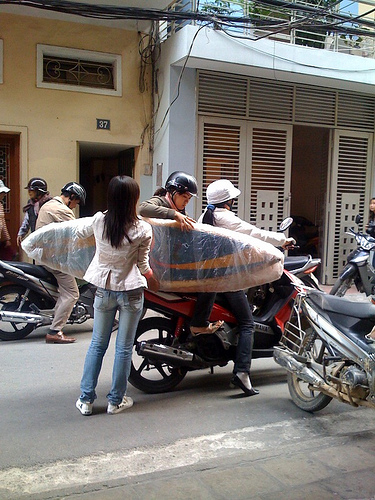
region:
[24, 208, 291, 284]
Woman holding a surf board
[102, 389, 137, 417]
woman wearing white sneakers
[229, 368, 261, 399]
woman wearing black shoes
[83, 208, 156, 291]
woman wearing a brown jacket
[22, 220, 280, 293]
plastic bag on the surfboard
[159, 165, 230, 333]
woman on the back of a bike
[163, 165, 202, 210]
woman wearing a black helmet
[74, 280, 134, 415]
woman wearing blue jeans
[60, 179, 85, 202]
man wearing a black helmet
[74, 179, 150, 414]
this is a person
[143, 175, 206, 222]
this is a person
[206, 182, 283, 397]
this is a person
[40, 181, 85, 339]
this is a person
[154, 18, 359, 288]
this is a building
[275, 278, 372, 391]
this is a motorcycle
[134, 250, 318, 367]
this is a notorcycle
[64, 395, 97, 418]
this is a shoe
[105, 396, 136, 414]
this is a shoe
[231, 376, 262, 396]
this is a shoe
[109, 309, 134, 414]
this is a leg of a person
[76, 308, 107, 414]
this is a leg of a person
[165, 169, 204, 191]
this is a helmet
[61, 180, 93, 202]
this is a helmet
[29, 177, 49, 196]
this is a helmet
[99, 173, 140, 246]
this is a person`s hair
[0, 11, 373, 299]
this is a bulding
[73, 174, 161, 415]
A girl in the street.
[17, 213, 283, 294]
Plastic on a surfboard.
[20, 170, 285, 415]
Two girls holding a surfboard.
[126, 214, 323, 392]
A red scooter on the street.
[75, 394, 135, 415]
A pair of shoes.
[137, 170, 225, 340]
A girl wearing a helmet.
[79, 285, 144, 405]
A pair of jeans.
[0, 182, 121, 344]
A guy on a scooter.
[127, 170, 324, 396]
Girls on a scooter.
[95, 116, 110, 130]
An address on a wall.